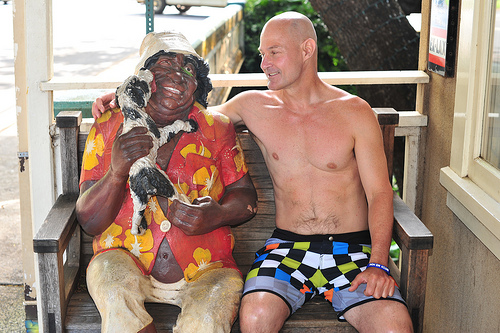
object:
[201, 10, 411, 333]
man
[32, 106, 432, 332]
bench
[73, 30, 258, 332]
statue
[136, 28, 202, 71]
hat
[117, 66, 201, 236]
dog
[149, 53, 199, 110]
face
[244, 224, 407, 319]
swim trunks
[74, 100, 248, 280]
hawaiian shirt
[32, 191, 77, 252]
armrest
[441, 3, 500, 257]
window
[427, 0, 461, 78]
board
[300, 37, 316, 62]
left ear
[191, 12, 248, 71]
fence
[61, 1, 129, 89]
street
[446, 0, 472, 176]
frame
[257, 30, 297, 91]
face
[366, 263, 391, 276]
band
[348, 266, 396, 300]
hand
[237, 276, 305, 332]
legs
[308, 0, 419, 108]
tree